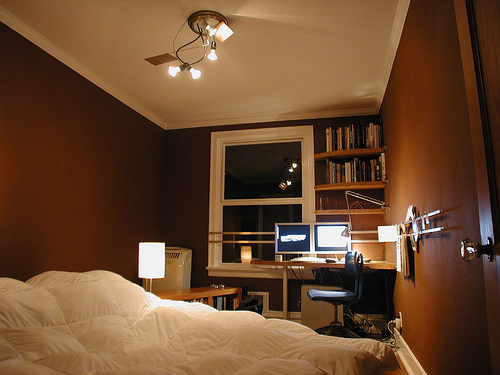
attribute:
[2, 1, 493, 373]
wall — brown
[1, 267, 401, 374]
comforter — white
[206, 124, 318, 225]
window panes — white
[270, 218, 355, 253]
computers — white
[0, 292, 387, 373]
quilt — white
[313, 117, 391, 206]
book shelf — neatly arranged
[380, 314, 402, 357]
wire cord — small, electric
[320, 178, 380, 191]
shelf — middle